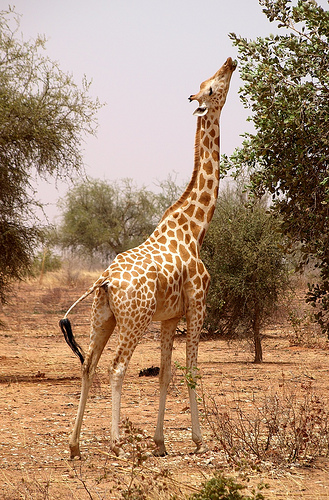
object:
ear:
[192, 103, 210, 115]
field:
[0, 271, 329, 500]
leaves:
[230, 33, 236, 39]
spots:
[178, 242, 190, 263]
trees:
[203, 184, 281, 368]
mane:
[158, 120, 201, 221]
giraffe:
[53, 53, 239, 458]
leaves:
[246, 115, 253, 123]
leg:
[66, 301, 116, 459]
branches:
[194, 362, 328, 470]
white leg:
[187, 381, 203, 441]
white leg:
[152, 380, 169, 443]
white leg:
[108, 365, 126, 455]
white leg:
[68, 375, 91, 446]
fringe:
[162, 117, 199, 223]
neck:
[182, 115, 221, 211]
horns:
[188, 92, 197, 102]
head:
[187, 58, 236, 111]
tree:
[216, 0, 329, 348]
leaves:
[271, 192, 277, 202]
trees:
[0, 5, 101, 336]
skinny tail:
[58, 263, 108, 368]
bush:
[191, 466, 248, 498]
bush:
[102, 415, 168, 498]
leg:
[109, 298, 153, 460]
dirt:
[1, 286, 326, 498]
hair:
[58, 318, 87, 364]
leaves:
[293, 266, 301, 273]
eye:
[209, 86, 213, 96]